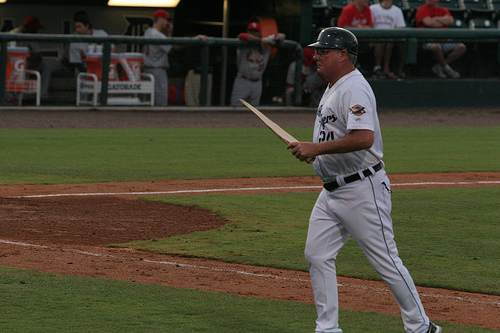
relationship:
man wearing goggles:
[280, 25, 446, 332] [315, 50, 358, 56]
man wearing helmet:
[280, 25, 446, 332] [307, 26, 361, 58]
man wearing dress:
[280, 25, 446, 332] [301, 67, 433, 332]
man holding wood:
[280, 25, 446, 332] [237, 96, 315, 164]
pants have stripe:
[305, 160, 431, 332] [367, 174, 427, 321]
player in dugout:
[68, 13, 116, 80] [1, 0, 311, 108]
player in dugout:
[140, 8, 208, 105] [1, 0, 311, 108]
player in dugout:
[4, 14, 54, 103] [1, 0, 311, 108]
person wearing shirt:
[415, 0, 466, 81] [416, 5, 452, 30]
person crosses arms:
[415, 0, 466, 81] [423, 15, 454, 25]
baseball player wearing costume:
[293, 20, 434, 331] [298, 68, 426, 331]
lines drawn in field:
[0, 230, 495, 322] [0, 107, 500, 333]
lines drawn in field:
[0, 210, 495, 322] [0, 107, 500, 333]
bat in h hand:
[240, 95, 298, 147] [287, 140, 315, 161]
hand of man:
[287, 140, 315, 161] [280, 25, 446, 332]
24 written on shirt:
[315, 126, 340, 154] [296, 69, 377, 191]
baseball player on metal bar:
[286, 25, 440, 333] [207, 28, 239, 49]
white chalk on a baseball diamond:
[2, 180, 497, 204] [0, 160, 499, 322]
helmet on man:
[305, 23, 361, 56] [280, 25, 446, 332]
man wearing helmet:
[280, 25, 446, 332] [304, 21, 361, 51]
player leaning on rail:
[229, 20, 286, 104] [3, 30, 305, 115]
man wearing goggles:
[280, 25, 446, 332] [314, 48, 331, 57]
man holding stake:
[280, 25, 446, 332] [234, 100, 301, 146]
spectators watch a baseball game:
[283, 2, 475, 47] [2, 2, 491, 331]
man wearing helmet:
[235, 25, 445, 332] [307, 26, 361, 58]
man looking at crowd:
[139, 10, 174, 105] [334, 0, 483, 30]